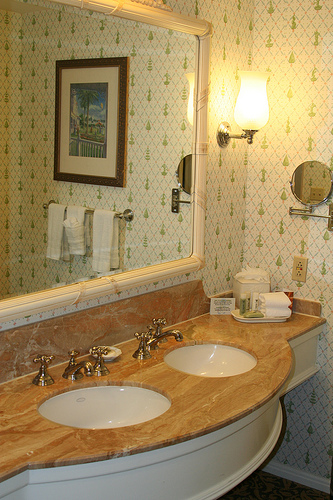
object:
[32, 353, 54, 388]
fixture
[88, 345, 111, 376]
fixture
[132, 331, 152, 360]
fixture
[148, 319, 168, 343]
fixture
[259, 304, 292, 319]
towel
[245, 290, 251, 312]
toiletry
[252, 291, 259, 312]
toiletry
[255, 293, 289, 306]
towels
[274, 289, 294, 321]
rack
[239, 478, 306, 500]
ground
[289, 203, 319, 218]
hinge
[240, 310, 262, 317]
soap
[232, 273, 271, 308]
tissueholder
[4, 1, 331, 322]
wallpaper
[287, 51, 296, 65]
tree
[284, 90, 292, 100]
tree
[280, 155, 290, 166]
tree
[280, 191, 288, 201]
tree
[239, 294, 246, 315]
bottle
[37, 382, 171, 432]
sink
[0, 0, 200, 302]
mirror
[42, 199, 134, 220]
towel bar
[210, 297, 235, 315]
card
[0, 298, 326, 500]
counter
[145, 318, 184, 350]
faucet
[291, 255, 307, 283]
outlet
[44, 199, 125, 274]
towels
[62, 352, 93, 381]
faucet head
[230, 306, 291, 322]
tray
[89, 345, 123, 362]
soap dish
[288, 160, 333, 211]
mirror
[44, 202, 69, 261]
towel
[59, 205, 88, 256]
towel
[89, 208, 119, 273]
towel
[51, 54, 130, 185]
frame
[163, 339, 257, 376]
sink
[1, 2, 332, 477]
wall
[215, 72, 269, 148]
lamp